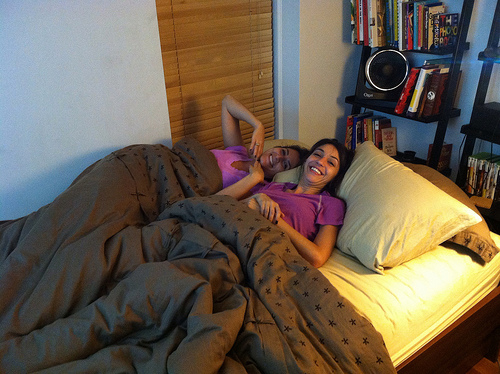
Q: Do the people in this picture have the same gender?
A: Yes, all the people are female.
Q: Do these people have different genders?
A: No, all the people are female.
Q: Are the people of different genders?
A: No, all the people are female.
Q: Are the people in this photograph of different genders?
A: No, all the people are female.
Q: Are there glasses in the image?
A: No, there are no glasses.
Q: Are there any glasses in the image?
A: No, there are no glasses.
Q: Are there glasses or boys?
A: No, there are no glasses or boys.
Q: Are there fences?
A: No, there are no fences.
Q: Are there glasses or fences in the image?
A: No, there are no fences or glasses.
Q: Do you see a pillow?
A: Yes, there is a pillow.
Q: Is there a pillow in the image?
A: Yes, there is a pillow.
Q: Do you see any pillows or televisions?
A: Yes, there is a pillow.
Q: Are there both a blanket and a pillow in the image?
A: Yes, there are both a pillow and a blanket.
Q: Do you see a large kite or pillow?
A: Yes, there is a large pillow.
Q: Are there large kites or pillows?
A: Yes, there is a large pillow.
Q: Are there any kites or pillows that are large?
A: Yes, the pillow is large.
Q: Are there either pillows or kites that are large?
A: Yes, the pillow is large.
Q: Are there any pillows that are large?
A: Yes, there is a large pillow.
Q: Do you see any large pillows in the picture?
A: Yes, there is a large pillow.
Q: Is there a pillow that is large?
A: Yes, there is a pillow that is large.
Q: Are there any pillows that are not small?
A: Yes, there is a large pillow.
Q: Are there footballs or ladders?
A: No, there are no ladders or footballs.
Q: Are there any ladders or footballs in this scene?
A: No, there are no ladders or footballs.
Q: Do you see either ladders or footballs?
A: No, there are no ladders or footballs.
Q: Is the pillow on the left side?
A: No, the pillow is on the right of the image.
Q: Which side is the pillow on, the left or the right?
A: The pillow is on the right of the image.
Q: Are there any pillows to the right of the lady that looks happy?
A: Yes, there is a pillow to the right of the lady.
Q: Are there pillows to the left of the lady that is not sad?
A: No, the pillow is to the right of the lady.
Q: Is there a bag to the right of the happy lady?
A: No, there is a pillow to the right of the lady.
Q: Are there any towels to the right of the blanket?
A: No, there is a pillow to the right of the blanket.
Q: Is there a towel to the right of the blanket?
A: No, there is a pillow to the right of the blanket.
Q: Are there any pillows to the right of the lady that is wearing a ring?
A: Yes, there is a pillow to the right of the lady.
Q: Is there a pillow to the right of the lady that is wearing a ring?
A: Yes, there is a pillow to the right of the lady.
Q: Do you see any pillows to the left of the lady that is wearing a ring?
A: No, the pillow is to the right of the lady.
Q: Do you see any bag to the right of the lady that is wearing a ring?
A: No, there is a pillow to the right of the lady.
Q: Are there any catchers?
A: No, there are no catchers.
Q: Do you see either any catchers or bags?
A: No, there are no catchers or bags.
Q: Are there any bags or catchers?
A: No, there are no catchers or bags.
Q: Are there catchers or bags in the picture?
A: No, there are no catchers or bags.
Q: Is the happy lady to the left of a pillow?
A: Yes, the lady is to the left of a pillow.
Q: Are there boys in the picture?
A: No, there are no boys.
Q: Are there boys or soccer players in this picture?
A: No, there are no boys or soccer players.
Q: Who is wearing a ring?
A: The lady is wearing a ring.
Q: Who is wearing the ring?
A: The lady is wearing a ring.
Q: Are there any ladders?
A: No, there are no ladders.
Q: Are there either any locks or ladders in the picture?
A: No, there are no ladders or locks.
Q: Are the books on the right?
A: Yes, the books are on the right of the image.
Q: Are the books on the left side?
A: No, the books are on the right of the image.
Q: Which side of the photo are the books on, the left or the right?
A: The books are on the right of the image.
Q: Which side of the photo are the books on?
A: The books are on the right of the image.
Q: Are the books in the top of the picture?
A: Yes, the books are in the top of the image.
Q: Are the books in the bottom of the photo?
A: No, the books are in the top of the image.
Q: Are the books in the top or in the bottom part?
A: The books are in the top of the image.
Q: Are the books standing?
A: Yes, the books are standing.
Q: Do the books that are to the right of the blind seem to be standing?
A: Yes, the books are standing.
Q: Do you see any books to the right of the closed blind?
A: Yes, there are books to the right of the blind.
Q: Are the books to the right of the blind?
A: Yes, the books are to the right of the blind.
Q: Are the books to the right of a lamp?
A: No, the books are to the right of the blind.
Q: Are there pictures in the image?
A: No, there are no pictures.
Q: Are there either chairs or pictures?
A: No, there are no pictures or chairs.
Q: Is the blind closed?
A: Yes, the blind is closed.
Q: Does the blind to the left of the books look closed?
A: Yes, the blind is closed.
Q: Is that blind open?
A: No, the blind is closed.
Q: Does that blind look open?
A: No, the blind is closed.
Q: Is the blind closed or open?
A: The blind is closed.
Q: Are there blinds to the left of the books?
A: Yes, there is a blind to the left of the books.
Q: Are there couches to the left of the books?
A: No, there is a blind to the left of the books.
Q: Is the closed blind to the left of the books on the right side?
A: Yes, the blind is to the left of the books.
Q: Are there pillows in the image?
A: Yes, there is a pillow.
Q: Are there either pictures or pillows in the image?
A: Yes, there is a pillow.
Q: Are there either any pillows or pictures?
A: Yes, there is a pillow.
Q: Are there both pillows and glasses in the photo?
A: No, there is a pillow but no glasses.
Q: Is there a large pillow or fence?
A: Yes, there is a large pillow.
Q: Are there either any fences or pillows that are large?
A: Yes, the pillow is large.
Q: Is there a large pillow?
A: Yes, there is a large pillow.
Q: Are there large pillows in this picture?
A: Yes, there is a large pillow.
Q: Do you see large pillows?
A: Yes, there is a large pillow.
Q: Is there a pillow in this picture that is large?
A: Yes, there is a pillow that is large.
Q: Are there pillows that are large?
A: Yes, there is a pillow that is large.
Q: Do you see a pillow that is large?
A: Yes, there is a pillow that is large.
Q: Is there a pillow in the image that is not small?
A: Yes, there is a large pillow.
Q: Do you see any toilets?
A: No, there are no toilets.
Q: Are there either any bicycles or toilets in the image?
A: No, there are no toilets or bicycles.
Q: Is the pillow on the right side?
A: Yes, the pillow is on the right of the image.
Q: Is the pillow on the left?
A: No, the pillow is on the right of the image.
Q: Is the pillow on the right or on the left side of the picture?
A: The pillow is on the right of the image.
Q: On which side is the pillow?
A: The pillow is on the right of the image.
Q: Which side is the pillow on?
A: The pillow is on the right of the image.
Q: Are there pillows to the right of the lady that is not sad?
A: Yes, there is a pillow to the right of the lady.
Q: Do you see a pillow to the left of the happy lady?
A: No, the pillow is to the right of the lady.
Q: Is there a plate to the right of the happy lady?
A: No, there is a pillow to the right of the lady.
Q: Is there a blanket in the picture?
A: Yes, there is a blanket.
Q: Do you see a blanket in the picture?
A: Yes, there is a blanket.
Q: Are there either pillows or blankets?
A: Yes, there is a blanket.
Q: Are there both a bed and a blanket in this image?
A: Yes, there are both a blanket and a bed.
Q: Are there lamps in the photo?
A: No, there are no lamps.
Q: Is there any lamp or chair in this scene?
A: No, there are no lamps or chairs.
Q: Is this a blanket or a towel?
A: This is a blanket.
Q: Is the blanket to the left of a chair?
A: No, the blanket is to the left of the pillow.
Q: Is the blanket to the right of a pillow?
A: No, the blanket is to the left of a pillow.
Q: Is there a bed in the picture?
A: Yes, there is a bed.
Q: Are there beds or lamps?
A: Yes, there is a bed.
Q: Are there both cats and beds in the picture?
A: No, there is a bed but no cats.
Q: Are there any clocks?
A: No, there are no clocks.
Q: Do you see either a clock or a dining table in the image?
A: No, there are no clocks or dining tables.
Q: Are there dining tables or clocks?
A: No, there are no clocks or dining tables.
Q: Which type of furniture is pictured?
A: The furniture is a bed.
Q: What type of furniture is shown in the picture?
A: The furniture is a bed.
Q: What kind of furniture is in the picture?
A: The furniture is a bed.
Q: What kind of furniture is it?
A: The piece of furniture is a bed.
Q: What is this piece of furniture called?
A: That is a bed.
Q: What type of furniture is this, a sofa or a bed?
A: That is a bed.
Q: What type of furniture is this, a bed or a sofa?
A: That is a bed.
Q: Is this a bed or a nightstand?
A: This is a bed.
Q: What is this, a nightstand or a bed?
A: This is a bed.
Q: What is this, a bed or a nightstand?
A: This is a bed.